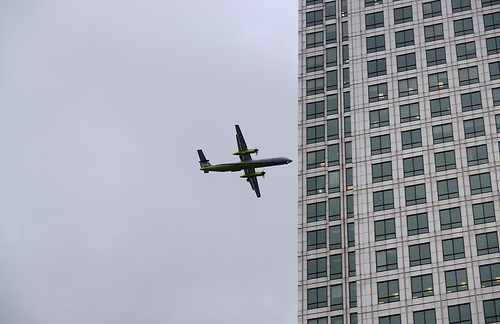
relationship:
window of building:
[305, 9, 323, 27] [295, 0, 499, 323]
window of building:
[307, 30, 327, 50] [295, 0, 499, 323]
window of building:
[305, 52, 325, 73] [295, 0, 499, 323]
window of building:
[305, 77, 326, 96] [295, 0, 499, 323]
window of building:
[307, 100, 325, 119] [295, 0, 499, 323]